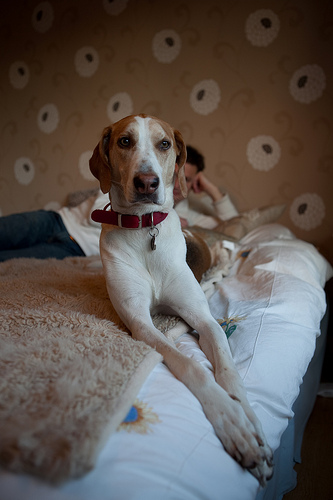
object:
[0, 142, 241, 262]
man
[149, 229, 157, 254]
tag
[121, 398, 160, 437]
flower design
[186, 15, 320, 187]
wallpaper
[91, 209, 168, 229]
collar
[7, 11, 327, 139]
flowers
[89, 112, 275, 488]
dog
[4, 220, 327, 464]
comforter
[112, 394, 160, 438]
flower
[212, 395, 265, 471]
paws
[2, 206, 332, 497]
bed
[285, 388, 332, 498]
carpet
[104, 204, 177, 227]
neck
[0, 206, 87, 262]
jeans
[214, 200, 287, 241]
brown pillow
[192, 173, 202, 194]
fist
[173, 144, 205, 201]
head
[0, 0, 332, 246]
wall